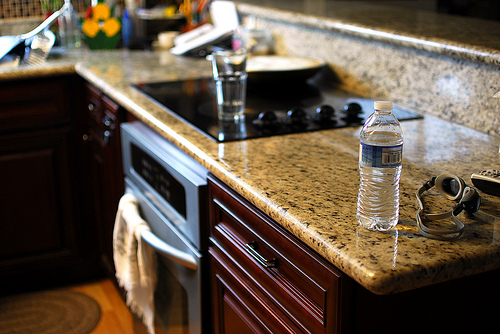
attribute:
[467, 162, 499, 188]
remote — half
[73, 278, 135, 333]
wood — light brown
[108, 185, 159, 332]
towel — white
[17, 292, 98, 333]
rug — small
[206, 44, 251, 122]
glass — clear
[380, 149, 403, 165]
barcode — black, white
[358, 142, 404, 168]
label — blue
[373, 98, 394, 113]
cap — white